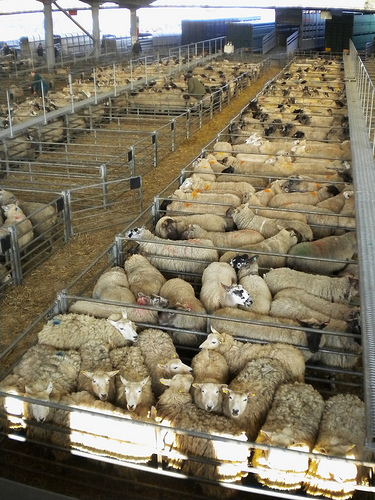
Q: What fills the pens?
A: Sheep.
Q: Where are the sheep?
A: In pens.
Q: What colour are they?
A: White.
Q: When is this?
A: Daytime.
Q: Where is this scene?
A: At a sheep farm.